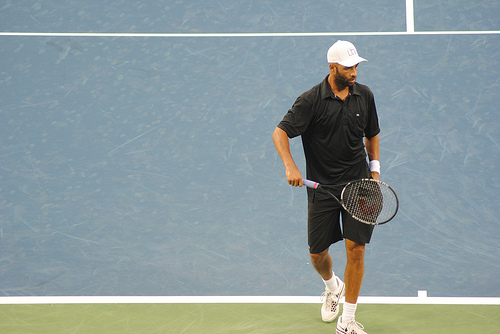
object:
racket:
[299, 176, 401, 224]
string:
[347, 180, 396, 224]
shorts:
[306, 179, 379, 253]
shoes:
[306, 276, 368, 333]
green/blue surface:
[0, 0, 499, 296]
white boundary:
[3, 5, 500, 303]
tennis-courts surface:
[3, 5, 482, 330]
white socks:
[321, 271, 360, 322]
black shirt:
[277, 80, 380, 189]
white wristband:
[368, 157, 382, 175]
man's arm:
[366, 97, 381, 188]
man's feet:
[311, 281, 383, 332]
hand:
[283, 168, 304, 187]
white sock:
[339, 298, 359, 320]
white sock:
[317, 272, 339, 292]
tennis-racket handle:
[302, 178, 321, 189]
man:
[271, 40, 400, 331]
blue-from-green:
[0, 0, 499, 297]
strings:
[339, 181, 397, 221]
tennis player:
[268, 37, 386, 332]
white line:
[0, 292, 500, 307]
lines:
[2, 294, 498, 310]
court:
[2, 2, 492, 332]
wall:
[17, 7, 484, 304]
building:
[0, 0, 499, 300]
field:
[0, 0, 499, 333]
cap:
[322, 37, 366, 67]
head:
[327, 39, 368, 86]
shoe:
[314, 279, 344, 321]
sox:
[320, 272, 341, 291]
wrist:
[372, 161, 381, 174]